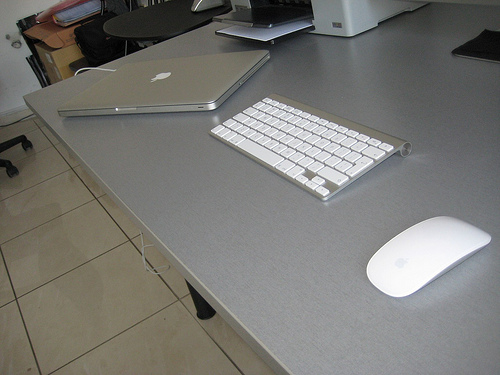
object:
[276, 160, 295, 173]
key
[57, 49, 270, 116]
laptop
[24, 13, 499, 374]
table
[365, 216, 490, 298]
mouse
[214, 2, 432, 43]
printer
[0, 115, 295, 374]
floor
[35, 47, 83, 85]
box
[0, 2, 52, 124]
wall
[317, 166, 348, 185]
key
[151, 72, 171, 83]
logo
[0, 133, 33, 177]
chair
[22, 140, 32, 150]
wheel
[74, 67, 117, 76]
cord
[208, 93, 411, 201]
key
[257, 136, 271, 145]
keyboard